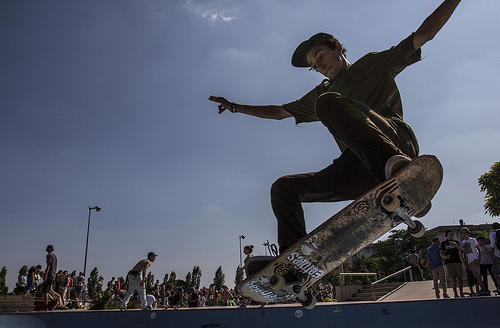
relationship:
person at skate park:
[425, 236, 449, 299] [2, 259, 498, 327]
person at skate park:
[442, 228, 468, 299] [2, 259, 498, 327]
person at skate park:
[459, 226, 490, 297] [2, 259, 498, 327]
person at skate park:
[41, 244, 60, 313] [2, 259, 498, 327]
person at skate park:
[121, 250, 157, 311] [2, 259, 498, 327]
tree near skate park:
[479, 159, 498, 215] [2, 259, 498, 327]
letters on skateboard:
[287, 252, 325, 281] [237, 152, 443, 312]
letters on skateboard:
[248, 280, 282, 303] [237, 152, 443, 312]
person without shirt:
[121, 250, 157, 311] [131, 258, 151, 275]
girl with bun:
[241, 244, 258, 270] [249, 245, 253, 249]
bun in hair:
[249, 245, 253, 249] [243, 245, 255, 254]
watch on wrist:
[231, 101, 236, 114] [228, 102, 240, 115]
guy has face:
[208, 2, 472, 273] [306, 44, 345, 81]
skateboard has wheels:
[237, 152, 443, 312] [381, 193, 425, 239]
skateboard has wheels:
[237, 152, 443, 312] [271, 275, 318, 311]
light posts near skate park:
[238, 233, 246, 274] [2, 259, 498, 327]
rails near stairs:
[370, 264, 414, 306] [348, 279, 405, 303]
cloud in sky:
[191, 4, 242, 26] [1, 5, 497, 285]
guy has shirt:
[208, 2, 472, 273] [282, 32, 423, 152]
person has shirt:
[459, 226, 490, 297] [459, 237, 481, 264]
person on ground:
[425, 236, 449, 299] [2, 301, 499, 326]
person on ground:
[41, 244, 60, 313] [2, 301, 499, 326]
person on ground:
[459, 226, 490, 297] [2, 301, 499, 326]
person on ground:
[182, 286, 200, 308] [2, 301, 499, 326]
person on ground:
[406, 250, 425, 282] [2, 301, 499, 326]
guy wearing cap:
[208, 2, 472, 273] [291, 33, 334, 69]